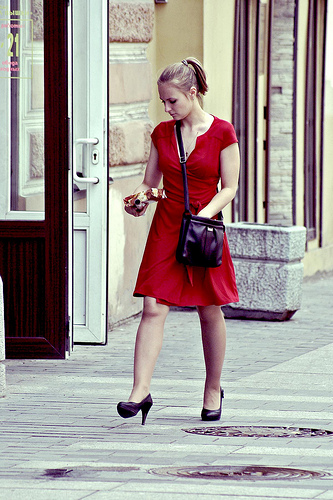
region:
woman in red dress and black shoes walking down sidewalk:
[109, 60, 238, 421]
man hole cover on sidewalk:
[149, 449, 332, 483]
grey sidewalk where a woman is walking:
[3, 333, 332, 499]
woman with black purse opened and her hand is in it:
[174, 115, 232, 269]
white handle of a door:
[70, 132, 101, 185]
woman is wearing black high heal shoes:
[116, 294, 232, 435]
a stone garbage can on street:
[227, 216, 306, 320]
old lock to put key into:
[86, 147, 100, 166]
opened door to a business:
[1, 2, 102, 353]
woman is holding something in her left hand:
[119, 143, 170, 222]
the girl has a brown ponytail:
[156, 55, 210, 121]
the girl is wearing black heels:
[115, 384, 222, 423]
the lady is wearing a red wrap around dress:
[133, 115, 242, 308]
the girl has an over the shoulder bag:
[162, 113, 238, 269]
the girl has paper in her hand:
[119, 160, 169, 223]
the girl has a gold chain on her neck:
[176, 112, 210, 160]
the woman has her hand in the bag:
[171, 194, 237, 279]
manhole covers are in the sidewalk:
[145, 422, 332, 483]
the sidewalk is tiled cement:
[18, 282, 331, 454]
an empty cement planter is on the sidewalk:
[221, 215, 307, 320]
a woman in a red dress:
[115, 53, 260, 310]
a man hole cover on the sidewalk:
[150, 444, 329, 499]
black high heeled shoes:
[97, 377, 246, 436]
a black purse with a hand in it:
[160, 120, 254, 280]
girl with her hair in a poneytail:
[144, 40, 224, 125]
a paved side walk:
[243, 330, 325, 414]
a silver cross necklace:
[170, 122, 211, 163]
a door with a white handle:
[67, 32, 125, 243]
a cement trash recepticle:
[223, 218, 312, 323]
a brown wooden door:
[2, 1, 63, 356]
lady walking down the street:
[93, 56, 261, 425]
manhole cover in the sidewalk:
[146, 458, 327, 489]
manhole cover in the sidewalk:
[178, 422, 331, 445]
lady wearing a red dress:
[93, 51, 249, 438]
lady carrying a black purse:
[86, 53, 263, 443]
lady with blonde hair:
[106, 54, 262, 431]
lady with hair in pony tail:
[88, 51, 266, 432]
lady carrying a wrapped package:
[94, 51, 252, 446]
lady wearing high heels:
[93, 54, 269, 430]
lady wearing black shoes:
[94, 48, 266, 432]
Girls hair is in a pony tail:
[140, 31, 214, 103]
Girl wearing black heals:
[101, 391, 251, 440]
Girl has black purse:
[170, 189, 242, 296]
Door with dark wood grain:
[4, 0, 77, 361]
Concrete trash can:
[214, 215, 316, 317]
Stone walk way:
[13, 342, 326, 484]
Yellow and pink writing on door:
[3, 8, 40, 91]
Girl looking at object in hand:
[146, 59, 199, 127]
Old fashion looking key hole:
[90, 146, 105, 168]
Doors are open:
[8, 5, 122, 371]